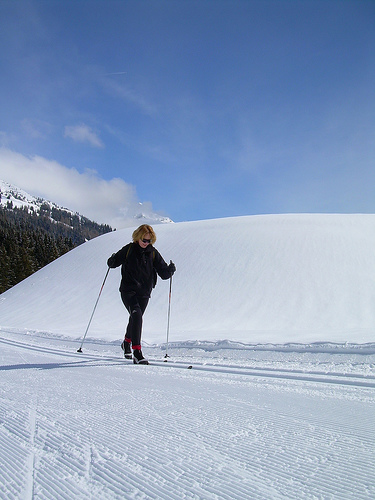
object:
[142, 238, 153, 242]
sunglasses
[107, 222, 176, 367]
woman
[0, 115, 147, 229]
clouds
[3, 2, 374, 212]
sky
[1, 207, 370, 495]
snow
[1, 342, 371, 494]
ground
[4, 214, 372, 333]
mound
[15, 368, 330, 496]
narrow ridges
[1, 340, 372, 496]
ski path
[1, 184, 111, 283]
mountain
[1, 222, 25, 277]
trees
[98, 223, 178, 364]
skier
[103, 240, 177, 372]
outfit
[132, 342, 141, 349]
cuff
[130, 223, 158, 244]
hair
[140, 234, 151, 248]
face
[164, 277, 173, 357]
ski pole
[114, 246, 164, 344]
body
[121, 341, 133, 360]
ski boots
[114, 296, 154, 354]
pants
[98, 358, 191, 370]
skis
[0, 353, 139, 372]
shadow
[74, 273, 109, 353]
poles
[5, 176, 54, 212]
snow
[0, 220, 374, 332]
mountain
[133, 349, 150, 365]
shoes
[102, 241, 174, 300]
jacket